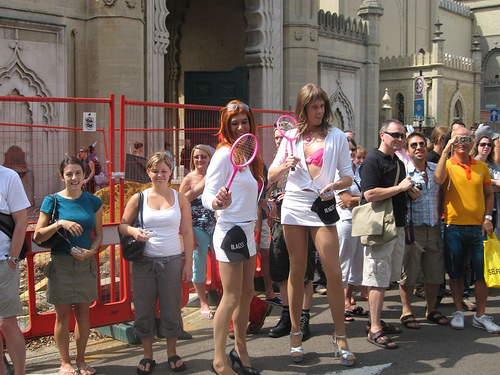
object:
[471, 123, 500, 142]
hat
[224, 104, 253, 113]
sunglasses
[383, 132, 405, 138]
sunglasses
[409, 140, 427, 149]
sunglasses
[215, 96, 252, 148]
head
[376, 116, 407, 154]
head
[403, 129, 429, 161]
head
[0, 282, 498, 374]
tarmac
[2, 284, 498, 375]
floor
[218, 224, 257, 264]
hat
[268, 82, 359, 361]
person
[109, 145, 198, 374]
person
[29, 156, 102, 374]
person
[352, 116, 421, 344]
person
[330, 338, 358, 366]
shoes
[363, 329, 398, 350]
shoes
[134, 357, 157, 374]
shoes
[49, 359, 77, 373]
shoes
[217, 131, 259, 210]
racket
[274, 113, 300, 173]
racket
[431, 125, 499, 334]
man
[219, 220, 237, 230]
pocket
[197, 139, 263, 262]
outfit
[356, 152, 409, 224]
shirt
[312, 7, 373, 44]
building roof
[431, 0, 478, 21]
building roof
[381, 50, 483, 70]
building roof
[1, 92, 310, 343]
fence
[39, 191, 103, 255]
blouse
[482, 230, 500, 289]
bag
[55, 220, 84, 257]
camera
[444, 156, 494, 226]
shirt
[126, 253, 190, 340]
short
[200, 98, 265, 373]
person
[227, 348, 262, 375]
heels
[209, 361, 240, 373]
heels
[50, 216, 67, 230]
wrist